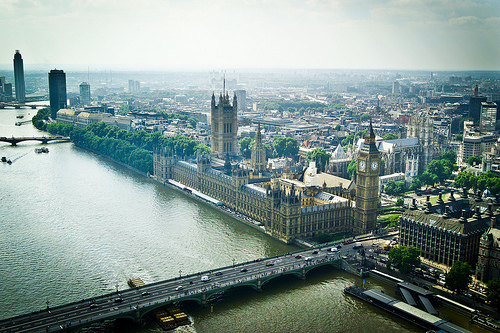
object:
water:
[19, 247, 60, 287]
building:
[13, 50, 25, 103]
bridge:
[2, 245, 346, 330]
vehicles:
[200, 276, 205, 278]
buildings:
[388, 205, 500, 284]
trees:
[127, 148, 152, 166]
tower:
[48, 68, 67, 121]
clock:
[358, 157, 366, 171]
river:
[3, 94, 430, 333]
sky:
[0, 1, 498, 75]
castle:
[154, 77, 382, 243]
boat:
[129, 277, 191, 330]